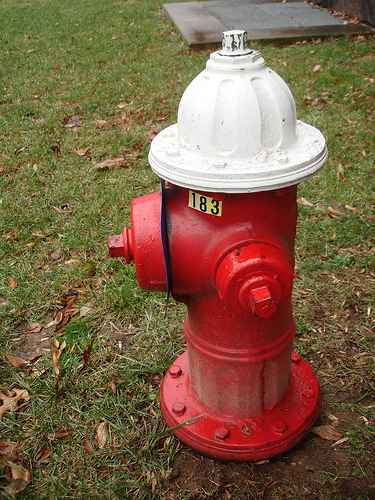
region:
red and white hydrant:
[125, 35, 333, 468]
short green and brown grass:
[33, 185, 75, 231]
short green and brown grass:
[47, 294, 110, 341]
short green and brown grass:
[57, 385, 100, 431]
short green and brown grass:
[40, 108, 73, 140]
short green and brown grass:
[73, 296, 115, 376]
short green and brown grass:
[31, 305, 70, 369]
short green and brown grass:
[16, 31, 56, 57]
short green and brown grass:
[62, 149, 115, 207]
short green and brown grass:
[20, 294, 63, 357]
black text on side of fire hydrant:
[184, 187, 231, 218]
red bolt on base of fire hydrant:
[202, 422, 235, 443]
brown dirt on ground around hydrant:
[286, 444, 317, 479]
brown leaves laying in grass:
[0, 352, 66, 423]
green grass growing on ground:
[14, 11, 145, 92]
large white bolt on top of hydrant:
[217, 25, 253, 56]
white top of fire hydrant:
[136, 35, 339, 193]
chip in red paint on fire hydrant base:
[236, 415, 262, 441]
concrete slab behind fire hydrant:
[156, 2, 368, 46]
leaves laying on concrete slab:
[308, 2, 364, 25]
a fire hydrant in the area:
[107, 30, 342, 485]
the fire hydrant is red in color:
[99, 23, 342, 469]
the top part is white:
[147, 30, 342, 198]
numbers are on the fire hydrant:
[180, 182, 221, 215]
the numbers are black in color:
[186, 191, 223, 215]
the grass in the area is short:
[1, 3, 341, 490]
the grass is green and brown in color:
[0, 1, 372, 491]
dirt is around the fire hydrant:
[152, 345, 373, 489]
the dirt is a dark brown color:
[141, 382, 367, 497]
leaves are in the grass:
[10, 5, 365, 492]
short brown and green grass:
[70, 393, 103, 432]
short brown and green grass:
[51, 55, 89, 106]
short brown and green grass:
[53, 10, 119, 74]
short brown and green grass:
[313, 241, 349, 288]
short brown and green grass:
[315, 45, 357, 72]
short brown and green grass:
[50, 85, 86, 133]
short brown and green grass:
[22, 150, 72, 217]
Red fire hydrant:
[93, 26, 353, 462]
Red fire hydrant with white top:
[105, 25, 348, 286]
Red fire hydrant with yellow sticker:
[86, 172, 373, 334]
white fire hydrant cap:
[140, 26, 349, 223]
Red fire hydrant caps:
[89, 190, 323, 330]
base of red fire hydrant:
[146, 329, 332, 472]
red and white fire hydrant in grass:
[82, 26, 372, 476]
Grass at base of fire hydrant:
[49, 321, 221, 461]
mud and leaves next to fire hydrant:
[185, 394, 373, 499]